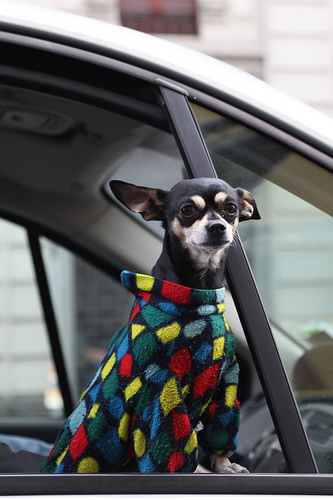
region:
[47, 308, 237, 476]
dog has sweater on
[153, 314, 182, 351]
yellow is on sweater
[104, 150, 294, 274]
dog looking at camera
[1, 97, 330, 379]
dog is in vechile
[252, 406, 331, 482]
steering wheel in the vehicle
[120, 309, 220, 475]
multiple colors on the dog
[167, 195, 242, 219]
dogs eyes are dark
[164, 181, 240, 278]
dog is black and white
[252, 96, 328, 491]
door frame is gray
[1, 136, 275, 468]
window is opened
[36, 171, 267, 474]
a dog wearing a multicolored shirt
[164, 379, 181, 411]
yellow diamond on the shirt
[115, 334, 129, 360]
a blue diamond on the shirt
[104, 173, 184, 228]
a large pointy ear on the dog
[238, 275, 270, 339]
black trim on the car window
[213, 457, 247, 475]
a small white paw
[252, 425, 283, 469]
the instrument panel in the car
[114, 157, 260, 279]
a black and brown dog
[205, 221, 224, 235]
a black snout on the dog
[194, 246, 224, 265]
a white patch on the neck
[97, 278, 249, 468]
the shirt is colorful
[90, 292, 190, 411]
the shirt is colorful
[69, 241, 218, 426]
the shirt is colorful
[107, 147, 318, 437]
the dog is looking outside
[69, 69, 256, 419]
the dog is looking outside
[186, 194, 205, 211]
the dog has tan eye brows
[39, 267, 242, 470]
the dog is wearing a multicolored jacket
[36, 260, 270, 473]
the jacket is yellow, red, blue and green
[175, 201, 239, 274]
the dogs muzzle is tan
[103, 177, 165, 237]
the dog ears are black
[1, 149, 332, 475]
the dog is in the car window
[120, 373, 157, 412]
the yellow square is shaped like a diamond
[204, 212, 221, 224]
the center of the nose is black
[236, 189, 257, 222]
the inside of the ear is tan and pink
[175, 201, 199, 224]
the dogs eye is black